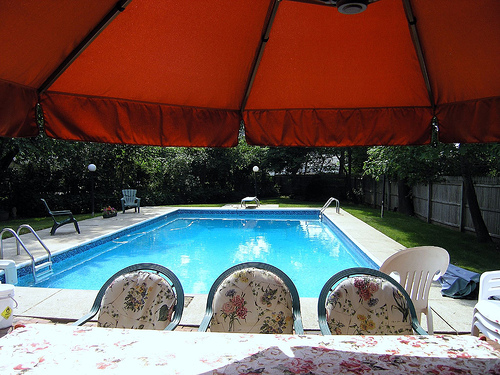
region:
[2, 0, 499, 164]
large red patio umbrella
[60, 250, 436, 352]
deck chairs with flowers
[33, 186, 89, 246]
green plastic deck chair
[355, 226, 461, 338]
white plastic deck chair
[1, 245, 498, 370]
floral patio table with chairs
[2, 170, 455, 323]
large in-ground swimming pool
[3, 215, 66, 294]
small metal pool ladder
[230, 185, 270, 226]
small pool diving board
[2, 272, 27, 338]
small white plastic bucket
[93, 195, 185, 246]
small potted plant near pool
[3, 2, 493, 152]
a red patio umbrella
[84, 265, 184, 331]
a padded patio chair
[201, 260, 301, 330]
a padded patio chair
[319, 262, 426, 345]
a padded patio chair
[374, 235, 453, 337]
a white plastic chair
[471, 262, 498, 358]
a stack of white plastic chairs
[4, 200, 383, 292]
a large blue pool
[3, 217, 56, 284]
a metal pool ladder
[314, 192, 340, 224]
a metal pool ladder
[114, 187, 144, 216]
a green patio chair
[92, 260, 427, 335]
Three chairs with floral print upholstery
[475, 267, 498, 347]
Stack of white resin chairs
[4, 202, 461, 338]
Swimming pool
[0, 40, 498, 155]
Red umbrella over table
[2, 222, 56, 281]
Swimming pool step ladder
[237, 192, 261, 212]
Swimming pool diving board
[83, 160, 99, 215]
Light pole with white globe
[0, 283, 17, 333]
White plastic pail containing an oxidizer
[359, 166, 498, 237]
Wooden privacy fence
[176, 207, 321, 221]
Blue tiles surrounding top of swimming pool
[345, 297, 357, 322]
the chair is floral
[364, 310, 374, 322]
the chair is floral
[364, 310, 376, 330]
the chair is floral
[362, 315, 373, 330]
the chair is floral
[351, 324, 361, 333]
the chair is floral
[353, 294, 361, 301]
the chair is floral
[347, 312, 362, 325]
the chair is floral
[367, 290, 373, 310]
the chair is floral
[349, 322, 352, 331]
the chair is floral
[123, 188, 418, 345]
Large swimming pool in backyard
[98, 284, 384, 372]
Outdoor tables and chairs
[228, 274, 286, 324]
Floral print with pink and yellow flowers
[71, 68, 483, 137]
Large umbrella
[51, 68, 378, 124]
The underside of the umbrella is red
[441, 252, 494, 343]
A stack of white plastic chairs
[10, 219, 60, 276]
Stairs that lead into the pool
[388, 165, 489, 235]
A wooden fence enclosing the yard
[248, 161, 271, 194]
Lamp posts for lighting at night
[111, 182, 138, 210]
Poolside outdoor lawn chairs